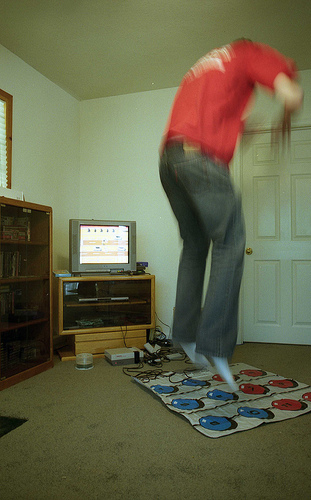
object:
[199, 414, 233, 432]
circle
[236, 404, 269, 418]
circle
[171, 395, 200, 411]
circle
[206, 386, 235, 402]
circle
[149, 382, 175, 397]
circle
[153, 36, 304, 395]
man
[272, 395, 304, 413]
button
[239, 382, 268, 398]
button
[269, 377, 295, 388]
button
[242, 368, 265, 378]
button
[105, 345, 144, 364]
video game console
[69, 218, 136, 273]
tv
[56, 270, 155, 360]
cabinet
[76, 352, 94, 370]
holder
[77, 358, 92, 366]
cd's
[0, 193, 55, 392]
bookcase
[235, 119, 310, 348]
door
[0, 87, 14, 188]
window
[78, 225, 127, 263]
television screen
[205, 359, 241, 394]
sock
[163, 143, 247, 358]
jeans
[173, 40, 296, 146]
t-shirt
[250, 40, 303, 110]
arm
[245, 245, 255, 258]
door knob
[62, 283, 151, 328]
door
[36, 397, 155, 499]
carpet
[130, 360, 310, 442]
game pad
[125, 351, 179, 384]
cord